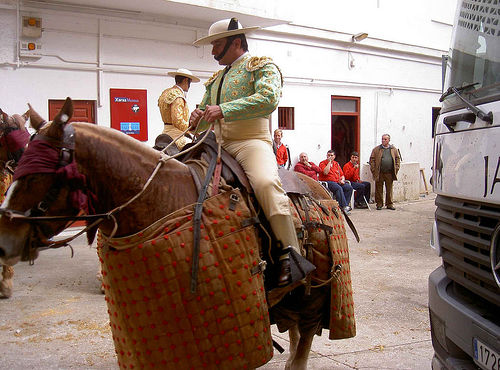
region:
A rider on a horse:
[189, 20, 307, 280]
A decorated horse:
[2, 95, 356, 368]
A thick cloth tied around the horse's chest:
[97, 187, 272, 369]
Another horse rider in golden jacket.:
[157, 67, 199, 148]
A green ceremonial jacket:
[197, 53, 283, 128]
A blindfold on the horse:
[11, 140, 84, 181]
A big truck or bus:
[427, 0, 498, 368]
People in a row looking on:
[274, 129, 401, 213]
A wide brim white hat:
[192, 18, 259, 42]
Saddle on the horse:
[202, 138, 307, 193]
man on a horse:
[9, 6, 433, 367]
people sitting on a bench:
[296, 148, 378, 210]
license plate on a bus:
[459, 329, 498, 364]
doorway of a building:
[324, 87, 366, 172]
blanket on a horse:
[89, 212, 289, 369]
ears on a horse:
[21, 88, 83, 140]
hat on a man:
[187, 5, 274, 45]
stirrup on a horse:
[273, 245, 325, 293]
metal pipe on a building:
[86, 17, 111, 106]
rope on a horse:
[151, 114, 218, 169]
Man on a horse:
[2, 3, 405, 367]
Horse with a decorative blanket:
[92, 192, 287, 356]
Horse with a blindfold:
[8, 124, 117, 226]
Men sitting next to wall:
[273, 127, 375, 202]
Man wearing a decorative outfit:
[193, 61, 330, 268]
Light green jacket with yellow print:
[203, 71, 290, 120]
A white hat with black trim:
[197, 8, 292, 58]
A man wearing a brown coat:
[366, 121, 404, 214]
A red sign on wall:
[106, 83, 159, 146]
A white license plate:
[468, 331, 498, 368]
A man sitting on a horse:
[2, 13, 364, 367]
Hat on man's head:
[186, 13, 265, 67]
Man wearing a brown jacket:
[366, 130, 407, 184]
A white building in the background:
[2, 2, 459, 197]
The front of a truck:
[424, 2, 498, 368]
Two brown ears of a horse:
[20, 90, 78, 131]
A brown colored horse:
[1, 95, 359, 367]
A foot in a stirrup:
[266, 242, 320, 292]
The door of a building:
[323, 88, 363, 168]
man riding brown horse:
[33, 15, 361, 331]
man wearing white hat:
[162, 5, 339, 291]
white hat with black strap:
[189, 12, 256, 59]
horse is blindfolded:
[16, 82, 384, 359]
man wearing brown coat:
[369, 130, 417, 219]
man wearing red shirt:
[348, 147, 374, 206]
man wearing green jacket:
[165, 13, 323, 275]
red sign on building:
[112, 78, 149, 135]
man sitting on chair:
[320, 147, 355, 209]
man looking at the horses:
[294, 148, 336, 213]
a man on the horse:
[146, 56, 192, 162]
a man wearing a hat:
[206, 11, 246, 77]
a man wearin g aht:
[158, 49, 210, 124]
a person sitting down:
[319, 142, 341, 192]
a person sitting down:
[331, 146, 360, 199]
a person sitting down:
[201, 54, 281, 223]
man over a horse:
[73, 131, 295, 270]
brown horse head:
[5, 147, 150, 220]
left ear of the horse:
[57, 110, 87, 128]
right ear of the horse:
[29, 105, 39, 121]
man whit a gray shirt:
[376, 134, 397, 182]